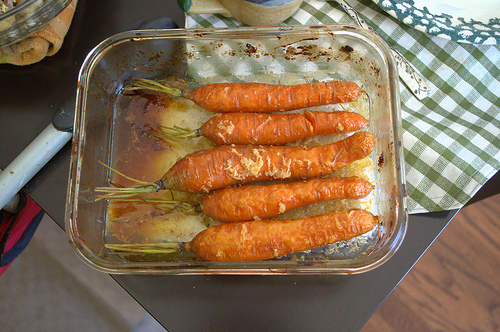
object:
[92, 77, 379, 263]
carrots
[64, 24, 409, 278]
pan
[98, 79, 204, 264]
roots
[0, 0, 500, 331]
floor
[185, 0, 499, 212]
cloth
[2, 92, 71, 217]
handle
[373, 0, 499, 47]
plate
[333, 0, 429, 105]
handle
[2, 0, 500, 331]
table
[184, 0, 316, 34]
mug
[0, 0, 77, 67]
towel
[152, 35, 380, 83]
bits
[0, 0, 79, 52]
bowl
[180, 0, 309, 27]
cup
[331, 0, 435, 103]
utensil